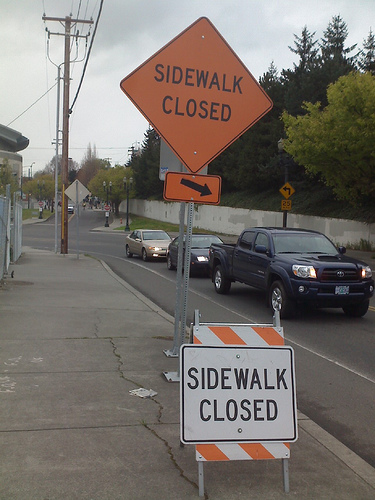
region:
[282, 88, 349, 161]
Trees are green color.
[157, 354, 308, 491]
Board is in sidewalk.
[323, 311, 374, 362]
Road is grey color.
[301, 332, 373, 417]
White color lines in road.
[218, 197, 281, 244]
Wall is white color.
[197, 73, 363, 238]
Trees are behind the wall.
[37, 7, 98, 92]
Power cords are passing is air.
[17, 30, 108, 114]
Sky is grey color.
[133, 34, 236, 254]
Board is attached to the pole.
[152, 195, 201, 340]
Pole is grey color.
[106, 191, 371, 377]
three vehicles on street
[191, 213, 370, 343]
truck is dark blue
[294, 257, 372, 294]
truck has lights on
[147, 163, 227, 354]
orange sign on pole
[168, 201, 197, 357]
pole is grey with holes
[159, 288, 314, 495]
orange and white sign on sidewalk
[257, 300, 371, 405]
thin line on street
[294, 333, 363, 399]
line on street is white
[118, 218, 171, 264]
last car is beige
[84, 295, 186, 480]
multiple cracks on sidewalk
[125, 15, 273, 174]
sidewalk closed sign on side of road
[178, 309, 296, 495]
sidewalk closed sign on actual sidewalk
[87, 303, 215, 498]
large cack in sidewalk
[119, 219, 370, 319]
vehicles back up in traffic on road near closed sidewalk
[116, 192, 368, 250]
brick walk used to establish property lines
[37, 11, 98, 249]
power lines indicating this place has electricity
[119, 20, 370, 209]
some trees and bushes to aid in privacy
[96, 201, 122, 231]
sidewalk back here is not closed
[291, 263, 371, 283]
truck has front lights on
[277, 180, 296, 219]
sign on road indicating left turn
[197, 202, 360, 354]
the car is black in colour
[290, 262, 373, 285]
the lights are on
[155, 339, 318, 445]
the sign is white in colour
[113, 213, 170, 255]
the car is brown in colour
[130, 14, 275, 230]
the sign is orange in colour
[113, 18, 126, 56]
the sky is cloudy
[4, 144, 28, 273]
the house is white in colour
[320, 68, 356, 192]
the trees are green in colour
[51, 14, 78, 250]
the post is brown in colour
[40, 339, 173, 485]
the floor is cracked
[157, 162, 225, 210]
THIS SIGN HAS A BLACK ARROW ON IT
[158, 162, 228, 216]
THIS SIGN IS ORANGE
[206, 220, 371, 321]
THIS TRUCK IS BLUE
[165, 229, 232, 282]
THIS CAR IS BLUE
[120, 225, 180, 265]
THIS CAR IS TAN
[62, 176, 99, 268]
THIS IS A STREET SIGN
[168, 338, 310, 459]
THIS SIGN IS ON THE SIDEWALK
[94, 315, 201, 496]
THIS IS A CRACK IN THE SIDEWALK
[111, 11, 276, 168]
THIS IS AN ORANGE SIGN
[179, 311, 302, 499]
THIS IS A CONSTRUCTION SIGN